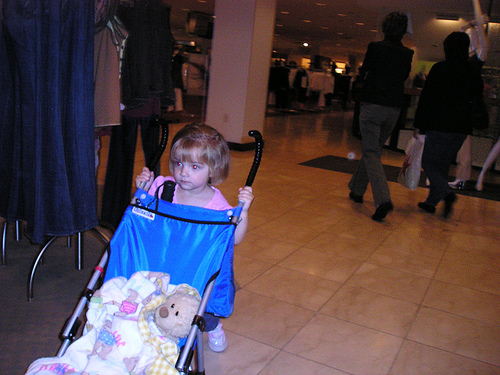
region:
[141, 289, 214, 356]
stuffed brown bear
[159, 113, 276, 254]
little girl pushing stroller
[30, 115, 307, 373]
royal blue stroller with bear in it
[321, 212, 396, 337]
brown marble tile on ground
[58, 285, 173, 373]
baby blankets covering stuffed bear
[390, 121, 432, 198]
white shopping bag with red star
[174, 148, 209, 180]
child with red eyes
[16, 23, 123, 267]
blue dress hanging on rack in store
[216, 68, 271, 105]
white column in middle of store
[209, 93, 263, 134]
white electrical outlet in middle column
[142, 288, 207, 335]
brown teddy bear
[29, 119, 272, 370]
blue stroller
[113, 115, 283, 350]
young girl pushing a blue stroller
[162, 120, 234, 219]
young girl wearing pink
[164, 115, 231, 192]
young girl with brown hair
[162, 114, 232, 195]
young girl with straight hair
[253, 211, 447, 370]
square tiles on the ground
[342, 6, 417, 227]
person walking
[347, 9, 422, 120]
person wearing black jacket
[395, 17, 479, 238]
person carrying a white bag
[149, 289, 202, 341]
stuffed animal in stroller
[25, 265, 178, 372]
child's blanket in stroller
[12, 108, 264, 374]
metal stroller with blue vinyl harness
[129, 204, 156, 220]
rectangular label on stroller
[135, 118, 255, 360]
little girl pushing stroller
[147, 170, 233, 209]
pink shirt on little girl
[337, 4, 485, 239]
people walking opposite direction of little girl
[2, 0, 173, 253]
clothes hanging on display rack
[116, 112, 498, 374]
marble floor in mall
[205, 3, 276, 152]
pillar in center of walkway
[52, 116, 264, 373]
A blue baby stroller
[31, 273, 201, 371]
A teddy bead under a blanket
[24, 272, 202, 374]
A toy bear sitting in a stroller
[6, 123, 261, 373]
A child pushing a stroller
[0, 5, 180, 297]
A clothing display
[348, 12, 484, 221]
Two people walking together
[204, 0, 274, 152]
A white pillar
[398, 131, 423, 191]
A plastic bag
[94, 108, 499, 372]
White stone tile floor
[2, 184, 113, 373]
Blue carpeted floor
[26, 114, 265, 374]
a little girl pushing stroller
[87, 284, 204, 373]
teddy bear in stroller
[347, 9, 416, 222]
a woman with black jacket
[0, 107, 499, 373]
brown floor tile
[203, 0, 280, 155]
black and white support beam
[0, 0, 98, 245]
part of a blue dress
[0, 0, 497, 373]
a large shopping center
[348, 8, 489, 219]
two women walking togather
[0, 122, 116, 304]
a metal clothes rack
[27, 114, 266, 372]
blue, black and silver stroller